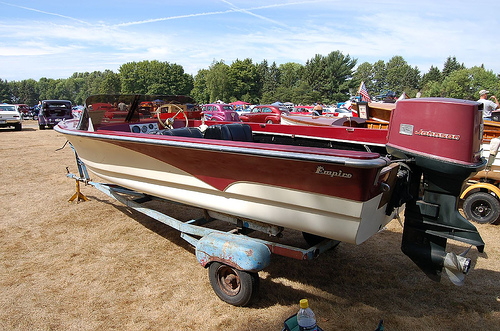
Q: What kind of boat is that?
A: A large red and white boat.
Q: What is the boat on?
A: A rusted blue stand with wheels.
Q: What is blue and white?
A: The sky.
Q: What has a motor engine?
A: A boat.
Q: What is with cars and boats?
A: Grass.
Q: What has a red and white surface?
A: A boat.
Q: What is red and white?
A: A boat.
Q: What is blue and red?
A: A trailer.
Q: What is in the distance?
A: Trees.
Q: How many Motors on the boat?
A: One.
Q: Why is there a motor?
A: Power.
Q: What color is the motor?
A: Red.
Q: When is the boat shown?
A: Daytime.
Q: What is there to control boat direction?
A: Steering wheel.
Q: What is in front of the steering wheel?
A: Windshield.